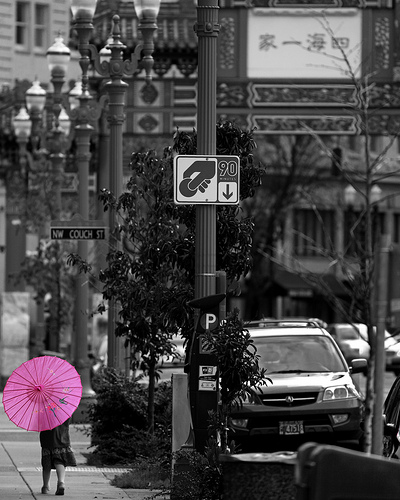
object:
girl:
[38, 404, 78, 498]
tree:
[104, 122, 265, 432]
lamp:
[72, 0, 161, 89]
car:
[210, 320, 374, 458]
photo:
[0, 0, 400, 500]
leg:
[43, 451, 66, 487]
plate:
[278, 419, 305, 437]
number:
[218, 160, 238, 178]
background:
[67, 54, 344, 299]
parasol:
[3, 354, 83, 431]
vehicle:
[363, 322, 400, 375]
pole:
[103, 81, 129, 383]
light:
[23, 28, 96, 133]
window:
[14, 3, 49, 50]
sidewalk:
[0, 410, 146, 500]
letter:
[174, 154, 241, 207]